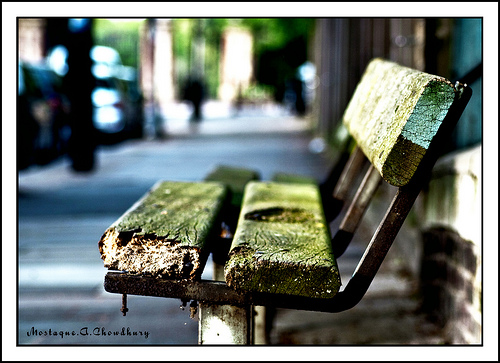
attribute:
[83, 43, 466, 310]
bench — wood, empty, old, green, black, brown, metal, worn, rusted, wooden, rusty, bolt, dirty, brick, sitting, back, pole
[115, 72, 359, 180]
street — empty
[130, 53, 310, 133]
sun — shining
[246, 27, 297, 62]
tree — leafy, green, blurry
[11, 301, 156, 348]
name — black, character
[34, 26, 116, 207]
pole — black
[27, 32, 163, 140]
car — parked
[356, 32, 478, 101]
window — teal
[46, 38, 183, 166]
vehicle — colored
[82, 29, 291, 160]
background — blurry